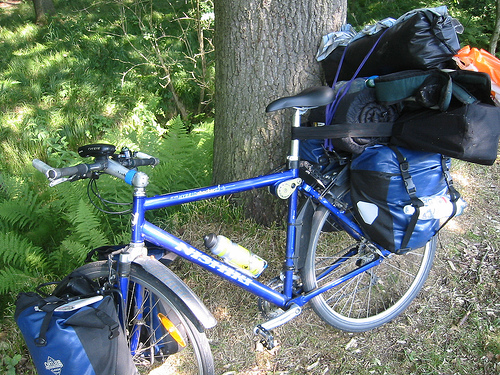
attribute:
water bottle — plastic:
[202, 231, 269, 281]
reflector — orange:
[146, 308, 187, 345]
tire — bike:
[20, 249, 227, 373]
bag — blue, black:
[13, 291, 127, 373]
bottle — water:
[197, 220, 272, 288]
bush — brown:
[81, 0, 221, 133]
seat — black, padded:
[262, 80, 341, 115]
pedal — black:
[254, 323, 277, 353]